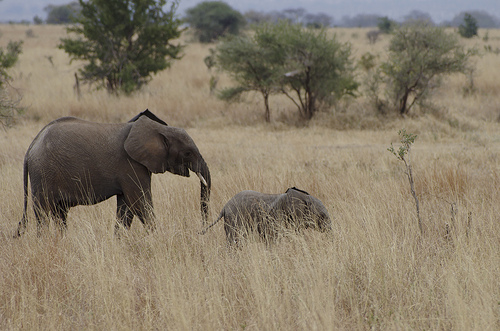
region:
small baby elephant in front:
[214, 179, 326, 244]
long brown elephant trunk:
[190, 131, 216, 237]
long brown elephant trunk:
[176, 152, 221, 229]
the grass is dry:
[151, 263, 258, 324]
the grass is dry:
[313, 239, 388, 329]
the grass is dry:
[341, 274, 379, 329]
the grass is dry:
[309, 275, 349, 320]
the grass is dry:
[290, 197, 337, 303]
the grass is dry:
[341, 287, 364, 327]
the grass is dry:
[296, 245, 366, 320]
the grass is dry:
[361, 252, 395, 328]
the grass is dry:
[305, 310, 327, 328]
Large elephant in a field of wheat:
[6, 105, 211, 247]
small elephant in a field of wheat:
[197, 184, 335, 256]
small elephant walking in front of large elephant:
[199, 184, 338, 256]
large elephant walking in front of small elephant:
[14, 102, 216, 256]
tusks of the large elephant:
[199, 175, 210, 190]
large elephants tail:
[6, 151, 33, 241]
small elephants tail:
[197, 207, 224, 234]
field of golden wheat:
[12, 157, 477, 322]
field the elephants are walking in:
[8, 90, 494, 306]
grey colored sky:
[257, 1, 408, 10]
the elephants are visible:
[112, 83, 363, 268]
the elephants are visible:
[101, 146, 276, 322]